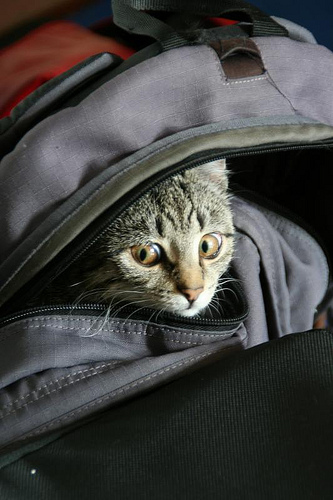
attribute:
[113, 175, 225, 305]
cat — gray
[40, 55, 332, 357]
back pack — unzipped, gray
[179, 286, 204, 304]
nose — pink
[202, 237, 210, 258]
pupil — diamond shaped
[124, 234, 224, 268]
eyes — brown, black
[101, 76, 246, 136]
material — blue, black